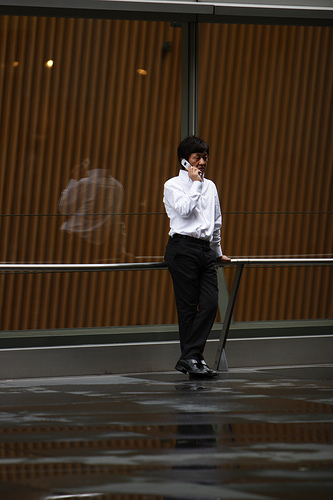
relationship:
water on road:
[2, 364, 331, 500] [0, 366, 331, 498]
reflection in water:
[175, 377, 219, 492] [2, 364, 331, 500]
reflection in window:
[59, 153, 139, 265] [0, 2, 332, 333]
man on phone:
[162, 135, 232, 379] [181, 156, 197, 172]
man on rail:
[162, 135, 232, 379] [1, 256, 332, 273]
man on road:
[162, 135, 232, 379] [0, 366, 331, 498]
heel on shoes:
[176, 360, 186, 376] [176, 355, 220, 382]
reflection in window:
[11, 56, 153, 77] [0, 2, 332, 333]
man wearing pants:
[162, 135, 232, 379] [163, 234, 219, 357]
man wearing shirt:
[162, 135, 232, 379] [164, 169, 228, 257]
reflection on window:
[11, 56, 153, 77] [0, 2, 332, 333]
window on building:
[0, 2, 332, 333] [2, 1, 333, 381]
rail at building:
[1, 256, 332, 273] [2, 1, 333, 381]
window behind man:
[0, 2, 332, 333] [162, 135, 232, 379]